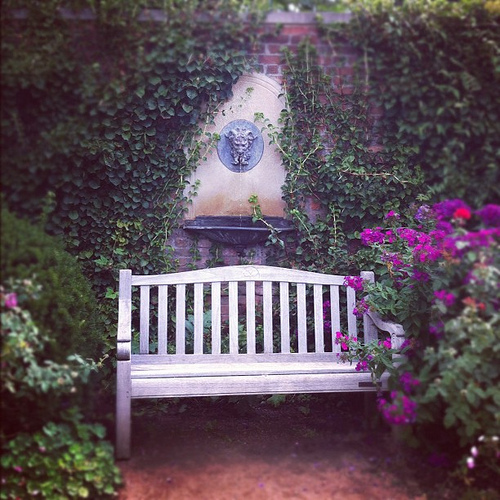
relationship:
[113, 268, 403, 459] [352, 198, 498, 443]
rest area in botanical garden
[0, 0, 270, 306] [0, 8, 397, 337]
plants on wall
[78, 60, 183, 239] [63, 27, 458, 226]
plants on wall